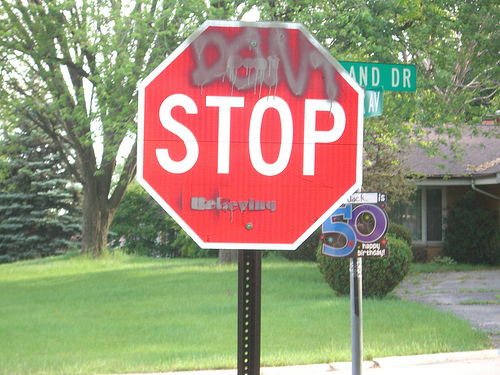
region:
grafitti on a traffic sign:
[176, 15, 350, 93]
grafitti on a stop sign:
[180, 32, 348, 88]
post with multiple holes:
[232, 242, 269, 373]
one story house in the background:
[321, 122, 494, 267]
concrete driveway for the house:
[391, 267, 497, 348]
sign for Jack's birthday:
[312, 184, 392, 261]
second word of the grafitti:
[172, 187, 288, 215]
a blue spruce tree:
[0, 111, 89, 269]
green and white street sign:
[333, 47, 435, 122]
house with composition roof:
[337, 117, 495, 268]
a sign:
[170, 134, 288, 361]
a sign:
[230, 150, 300, 356]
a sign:
[245, 175, 265, 220]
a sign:
[195, 112, 242, 298]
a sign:
[235, 165, 256, 250]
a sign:
[215, 85, 296, 285]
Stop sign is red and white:
[141, 63, 368, 249]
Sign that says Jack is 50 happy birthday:
[322, 205, 393, 255]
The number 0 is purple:
[348, 202, 389, 244]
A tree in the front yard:
[61, 135, 132, 260]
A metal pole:
[340, 252, 385, 370]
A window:
[407, 195, 447, 240]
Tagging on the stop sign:
[185, 30, 341, 90]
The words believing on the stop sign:
[175, 182, 290, 225]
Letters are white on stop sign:
[155, 100, 345, 175]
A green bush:
[373, 261, 398, 290]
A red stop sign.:
[106, 7, 373, 280]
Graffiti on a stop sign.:
[131, 12, 372, 268]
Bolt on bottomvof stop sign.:
[236, 216, 265, 234]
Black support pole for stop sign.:
[226, 248, 281, 373]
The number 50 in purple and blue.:
[319, 205, 392, 261]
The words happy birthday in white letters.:
[351, 239, 391, 262]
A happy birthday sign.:
[321, 190, 398, 267]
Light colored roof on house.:
[373, 112, 495, 199]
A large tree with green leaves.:
[6, 6, 160, 279]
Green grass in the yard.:
[12, 251, 446, 359]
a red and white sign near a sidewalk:
[131, 14, 366, 373]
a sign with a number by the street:
[318, 202, 393, 373]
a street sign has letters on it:
[330, 57, 417, 121]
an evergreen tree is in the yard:
[3, 120, 118, 269]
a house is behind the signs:
[303, 109, 499, 301]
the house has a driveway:
[403, 230, 498, 368]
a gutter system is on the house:
[371, 173, 499, 201]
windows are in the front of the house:
[381, 180, 461, 275]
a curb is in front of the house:
[150, 345, 499, 374]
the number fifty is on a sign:
[319, 199, 389, 374]